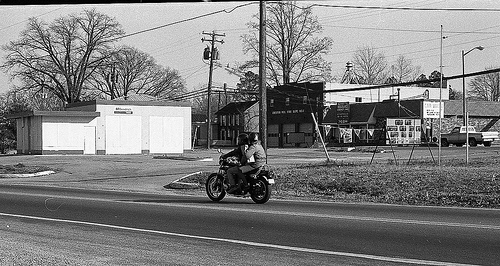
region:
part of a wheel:
[257, 179, 271, 206]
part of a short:
[236, 147, 260, 177]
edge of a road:
[373, 186, 412, 204]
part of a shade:
[154, 187, 209, 222]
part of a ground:
[301, 155, 344, 194]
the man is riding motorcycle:
[190, 105, 411, 225]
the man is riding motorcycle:
[200, 125, 272, 197]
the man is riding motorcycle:
[130, 70, 250, 241]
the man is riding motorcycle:
[212, 143, 302, 233]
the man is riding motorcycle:
[160, 66, 300, 222]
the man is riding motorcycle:
[195, 90, 286, 255]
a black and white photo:
[5, 7, 485, 257]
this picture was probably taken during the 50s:
[33, 48, 481, 218]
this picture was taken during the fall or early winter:
[5, 10, 475, 147]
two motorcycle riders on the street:
[30, 119, 469, 238]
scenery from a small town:
[207, 55, 497, 177]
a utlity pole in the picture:
[185, 22, 236, 149]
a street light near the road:
[443, 32, 497, 160]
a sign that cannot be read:
[381, 111, 437, 153]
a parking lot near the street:
[10, 140, 207, 199]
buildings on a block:
[186, 92, 320, 150]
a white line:
[159, 210, 222, 264]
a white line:
[260, 217, 315, 259]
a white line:
[254, 213, 293, 253]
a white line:
[244, 197, 290, 257]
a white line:
[214, 174, 283, 259]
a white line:
[249, 236, 270, 261]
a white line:
[265, 182, 310, 259]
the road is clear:
[210, 212, 341, 256]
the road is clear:
[315, 217, 380, 249]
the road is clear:
[249, 137, 381, 241]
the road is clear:
[260, 210, 328, 258]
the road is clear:
[253, 194, 360, 256]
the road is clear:
[273, 134, 360, 206]